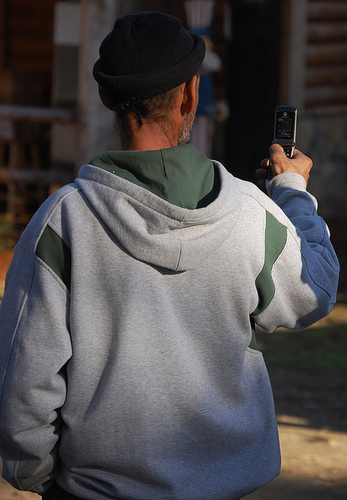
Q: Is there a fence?
A: No, there are no fences.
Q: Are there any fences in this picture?
A: No, there are no fences.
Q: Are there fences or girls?
A: No, there are no fences or girls.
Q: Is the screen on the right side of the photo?
A: Yes, the screen is on the right of the image.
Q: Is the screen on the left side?
A: No, the screen is on the right of the image.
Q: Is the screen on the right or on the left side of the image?
A: The screen is on the right of the image.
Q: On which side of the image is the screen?
A: The screen is on the right of the image.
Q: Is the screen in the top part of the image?
A: Yes, the screen is in the top of the image.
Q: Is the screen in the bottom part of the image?
A: No, the screen is in the top of the image.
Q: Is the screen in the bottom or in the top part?
A: The screen is in the top of the image.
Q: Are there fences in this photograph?
A: No, there are no fences.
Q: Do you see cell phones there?
A: Yes, there is a cell phone.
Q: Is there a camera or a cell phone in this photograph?
A: Yes, there is a cell phone.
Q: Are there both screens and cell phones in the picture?
A: Yes, there are both a cell phone and a screen.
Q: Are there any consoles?
A: No, there are no consoles.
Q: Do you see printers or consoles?
A: No, there are no consoles or printers.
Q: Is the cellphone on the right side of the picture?
A: Yes, the cellphone is on the right of the image.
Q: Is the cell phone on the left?
A: No, the cell phone is on the right of the image.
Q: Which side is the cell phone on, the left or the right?
A: The cell phone is on the right of the image.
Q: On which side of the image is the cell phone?
A: The cell phone is on the right of the image.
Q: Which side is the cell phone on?
A: The cell phone is on the right of the image.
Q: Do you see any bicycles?
A: No, there are no bicycles.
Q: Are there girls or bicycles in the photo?
A: No, there are no bicycles or girls.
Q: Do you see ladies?
A: No, there are no ladies.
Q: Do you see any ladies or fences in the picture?
A: No, there are no ladies or fences.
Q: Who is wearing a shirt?
A: The man is wearing a shirt.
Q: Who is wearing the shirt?
A: The man is wearing a shirt.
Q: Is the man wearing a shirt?
A: Yes, the man is wearing a shirt.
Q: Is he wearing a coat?
A: No, the man is wearing a shirt.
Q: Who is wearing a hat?
A: The man is wearing a hat.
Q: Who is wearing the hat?
A: The man is wearing a hat.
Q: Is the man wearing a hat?
A: Yes, the man is wearing a hat.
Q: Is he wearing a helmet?
A: No, the man is wearing a hat.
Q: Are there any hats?
A: Yes, there is a hat.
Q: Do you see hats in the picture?
A: Yes, there is a hat.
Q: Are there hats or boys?
A: Yes, there is a hat.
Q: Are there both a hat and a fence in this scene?
A: No, there is a hat but no fences.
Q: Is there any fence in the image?
A: No, there are no fences.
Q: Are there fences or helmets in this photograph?
A: No, there are no fences or helmets.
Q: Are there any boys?
A: No, there are no boys.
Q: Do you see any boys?
A: No, there are no boys.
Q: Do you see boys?
A: No, there are no boys.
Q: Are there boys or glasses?
A: No, there are no boys or glasses.